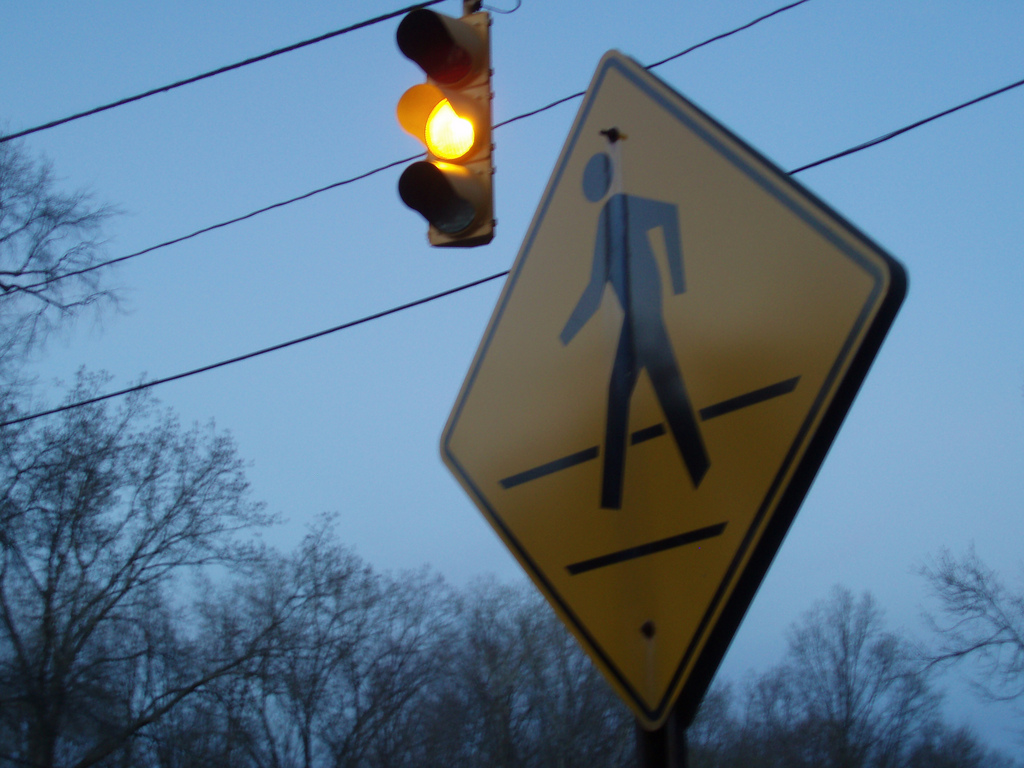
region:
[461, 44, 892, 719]
large diamond shape sign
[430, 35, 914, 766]
cross walk sign on a pole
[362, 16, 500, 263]
yellow traffic light hanging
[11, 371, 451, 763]
trees next to each other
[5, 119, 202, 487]
tree branches and wires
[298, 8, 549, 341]
traffic signal light with wires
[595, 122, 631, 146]
bolt on cross walk sign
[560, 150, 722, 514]
man on cross walk sign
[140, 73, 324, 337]
wires with clear skies behind them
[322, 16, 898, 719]
traffic signal near cautionary yellow sign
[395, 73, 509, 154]
The yellow traffic light.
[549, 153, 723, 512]
A drawing of a pedestrian.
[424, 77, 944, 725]
The pedestrian walking sign.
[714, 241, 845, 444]
Yellow sign with black artwork.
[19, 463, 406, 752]
Group of trees without leaves.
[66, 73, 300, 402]
Three black utility lines.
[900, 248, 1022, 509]
The early evening sky.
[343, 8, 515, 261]
The main traffic light.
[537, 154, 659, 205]
Head of the pedestrian.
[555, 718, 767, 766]
The pole of the street sign.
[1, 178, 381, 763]
Tree tops with no leaves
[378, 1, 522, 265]
Yellow traffic light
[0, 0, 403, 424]
Three utility type wires in the sky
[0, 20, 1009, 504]
Blue sky with no clouds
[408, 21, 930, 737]
Pedestrian crossing traffic sign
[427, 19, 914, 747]
Square shaped sign made of metal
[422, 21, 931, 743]
Yellow metal sign with black graphics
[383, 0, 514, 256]
Traffic light with the caution light lit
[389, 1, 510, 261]
Traffic light made of metal and painted yellow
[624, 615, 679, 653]
Screw located at bottom of sign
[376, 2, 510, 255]
The light is yellow.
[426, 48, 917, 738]
The street sign is yellow.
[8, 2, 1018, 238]
There are black wires.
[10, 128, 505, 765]
There are tress with no leaves.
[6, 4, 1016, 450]
There are 3 black wires.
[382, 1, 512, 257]
Two lights are out, one is yellow.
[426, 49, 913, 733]
There is a picture on the sign.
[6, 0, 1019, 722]
The sky is blue.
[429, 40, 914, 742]
The sign shows a picture of someone walking.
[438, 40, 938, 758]
The sign is triangle.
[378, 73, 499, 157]
yellow traffic light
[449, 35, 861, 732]
yellow cross walk sign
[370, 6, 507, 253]
hanging traffic signal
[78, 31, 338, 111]
piece of wire suspended in air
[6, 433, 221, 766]
tall tree with no leaves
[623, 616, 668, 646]
bolt on cross walk sign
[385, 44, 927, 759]
cautionary yellow sign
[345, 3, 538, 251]
traffic light about to turn red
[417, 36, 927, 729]
sign with sky in background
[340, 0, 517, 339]
traffic light with wires behind it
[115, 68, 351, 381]
three lines suspended overhead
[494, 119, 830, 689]
yellow pedestrian crossing sign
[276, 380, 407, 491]
darkening sky in the background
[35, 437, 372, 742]
dark trees silhouetted against the blue sky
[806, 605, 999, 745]
trees with no leaves on them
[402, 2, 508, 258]
a street traffic light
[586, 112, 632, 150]
a screw holding the sign in place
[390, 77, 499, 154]
the yellow light is lit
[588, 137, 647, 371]
two dark lines running across figure on sign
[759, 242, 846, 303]
yellow paint on the sign